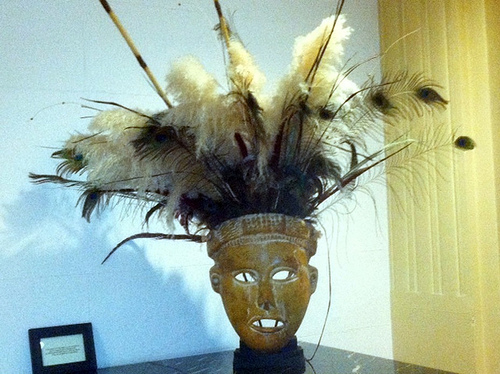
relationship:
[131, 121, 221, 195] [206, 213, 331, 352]
feathers on top of sculpture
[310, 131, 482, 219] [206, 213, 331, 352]
feathers on top of sculpture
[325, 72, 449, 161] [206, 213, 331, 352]
feathers on top of sculpture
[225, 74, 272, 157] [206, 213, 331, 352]
feathers on top of sculpture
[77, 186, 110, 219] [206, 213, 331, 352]
feathers on top of sculpture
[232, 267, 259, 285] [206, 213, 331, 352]
eyehole on sculpture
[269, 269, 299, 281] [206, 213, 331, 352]
eyehole on sculpture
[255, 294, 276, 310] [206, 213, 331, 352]
nose on sculpture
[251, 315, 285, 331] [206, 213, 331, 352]
mouthhole of sculpture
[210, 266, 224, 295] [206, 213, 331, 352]
ear of sculpture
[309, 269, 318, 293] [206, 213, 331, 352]
ear of sculpture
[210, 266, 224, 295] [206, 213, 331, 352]
ear on sculpture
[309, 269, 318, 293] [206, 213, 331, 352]
ear on sculpture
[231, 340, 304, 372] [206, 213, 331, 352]
stand of sculpture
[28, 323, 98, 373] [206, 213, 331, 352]
sign beside sculpture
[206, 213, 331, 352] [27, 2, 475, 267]
sculpture underneath headdress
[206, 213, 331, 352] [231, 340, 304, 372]
sculpture on stand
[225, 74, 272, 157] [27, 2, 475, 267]
feathers on headdress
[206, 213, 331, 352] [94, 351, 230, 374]
sculpture on table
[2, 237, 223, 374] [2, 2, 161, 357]
shadow on wall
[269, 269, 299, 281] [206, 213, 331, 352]
eyehole on mask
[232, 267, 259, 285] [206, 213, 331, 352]
eyehole of sculpture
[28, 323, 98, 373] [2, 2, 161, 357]
sign leaning on wall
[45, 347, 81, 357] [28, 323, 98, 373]
letters on sign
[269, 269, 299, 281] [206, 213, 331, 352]
eyehole of sculpture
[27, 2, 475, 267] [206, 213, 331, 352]
headdress on sculpture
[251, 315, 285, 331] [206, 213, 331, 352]
mouthhole on sculpture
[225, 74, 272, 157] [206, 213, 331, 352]
feathers in sculpture